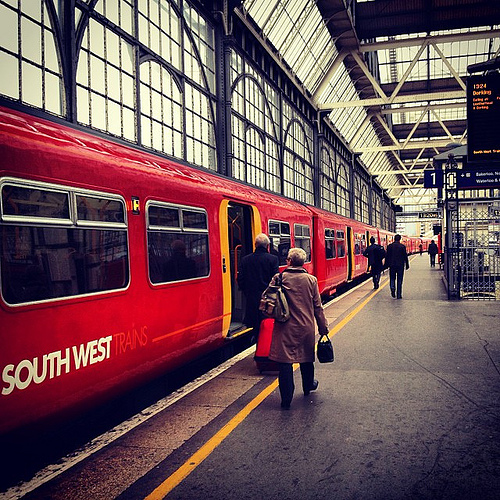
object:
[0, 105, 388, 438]
train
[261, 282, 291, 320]
backpack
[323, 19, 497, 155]
ceiling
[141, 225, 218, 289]
window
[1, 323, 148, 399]
logo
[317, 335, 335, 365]
handbag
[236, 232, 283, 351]
man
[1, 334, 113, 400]
lettering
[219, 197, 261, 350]
door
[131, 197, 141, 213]
light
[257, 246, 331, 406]
lady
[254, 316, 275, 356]
bag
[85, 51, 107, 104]
window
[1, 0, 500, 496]
station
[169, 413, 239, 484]
line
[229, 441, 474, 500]
floor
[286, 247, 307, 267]
head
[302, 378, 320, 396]
shoe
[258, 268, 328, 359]
coat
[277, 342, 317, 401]
pants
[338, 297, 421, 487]
sidewalk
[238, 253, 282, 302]
jacket